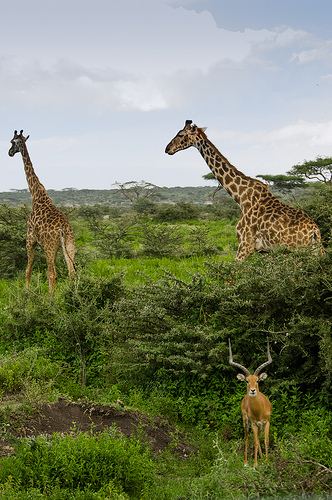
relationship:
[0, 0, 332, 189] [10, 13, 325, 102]
cloud in sky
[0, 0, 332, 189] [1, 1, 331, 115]
cloud in sky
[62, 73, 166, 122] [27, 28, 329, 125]
cloud in sky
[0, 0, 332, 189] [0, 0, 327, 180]
cloud in sky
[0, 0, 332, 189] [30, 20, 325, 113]
cloud in sky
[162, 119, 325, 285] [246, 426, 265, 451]
animal has legs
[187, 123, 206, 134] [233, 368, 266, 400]
horns on head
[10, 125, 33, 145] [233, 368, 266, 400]
horns on head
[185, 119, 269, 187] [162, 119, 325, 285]
neck hair down back of animal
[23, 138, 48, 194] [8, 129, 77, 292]
neck hair down back of animal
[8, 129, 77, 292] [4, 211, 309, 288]
animal standing in grass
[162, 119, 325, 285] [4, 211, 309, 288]
animal standing in grass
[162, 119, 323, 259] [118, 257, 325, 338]
animal standing near greenery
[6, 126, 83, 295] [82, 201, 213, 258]
animal standing near greenery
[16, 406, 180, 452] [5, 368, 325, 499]
dirt on ground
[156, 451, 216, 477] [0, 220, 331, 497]
grass on ground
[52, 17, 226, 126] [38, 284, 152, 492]
sky above land